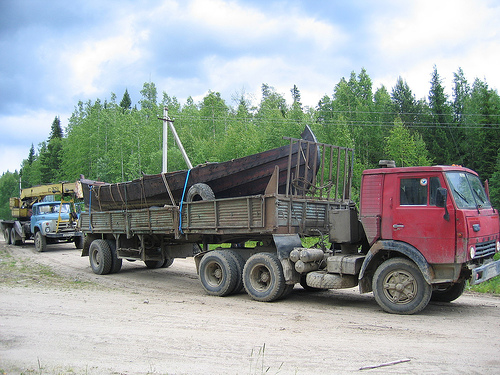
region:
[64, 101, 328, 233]
a boat out of water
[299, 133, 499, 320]
a dirty truck cab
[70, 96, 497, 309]
at least a 14 wheeler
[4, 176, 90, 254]
an old blue truck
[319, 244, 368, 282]
a large fuel tank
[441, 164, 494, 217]
visible windshield wiper path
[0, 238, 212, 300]
a muddy road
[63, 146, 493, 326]
a truck parked in a rural area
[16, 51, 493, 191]
a forest of evergreen trees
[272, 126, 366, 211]
a metal railing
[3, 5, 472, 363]
The picture is taken outside.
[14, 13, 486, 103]
The sky is blue with white clouds.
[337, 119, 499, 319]
The truck's cab is red in color.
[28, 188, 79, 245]
The truck's cab is blue in color.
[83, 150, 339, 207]
The truck is hauling a wood boat.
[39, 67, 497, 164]
The green trees are high and full of leaves.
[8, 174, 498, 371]
The truck are driving on dirt.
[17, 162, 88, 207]
The truck has a yellow crane on top.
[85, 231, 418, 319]
The truck's wheels are black but covered in dust and dirt.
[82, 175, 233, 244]
The straps holding the boat are blue in color.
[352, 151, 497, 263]
RED TRUCK CABIN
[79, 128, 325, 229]
TOWING AN OLD WOODEN BOAT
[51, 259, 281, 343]
WORN DIRT ROAD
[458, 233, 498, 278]
FRONT GRILLE OF A RED TRUCK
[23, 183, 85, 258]
BLUE TRUCK BEHIND LARGER TRUCK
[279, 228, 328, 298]
CYLINDERS LOADED ON TRUCK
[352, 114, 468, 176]
PINE TREES IN DISTANCE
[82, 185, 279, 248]
OLD STEEL FLATBED TRUCK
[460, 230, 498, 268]
HEADLIGHTS ON A RED TRUCK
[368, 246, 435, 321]
WHEEL CAP ON TRUCK TIRE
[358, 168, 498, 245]
the front of truck is red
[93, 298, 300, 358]
the ground is sandy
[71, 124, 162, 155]
the trees are green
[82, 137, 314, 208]
the boat is on the truck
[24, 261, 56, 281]
patches of grass on ground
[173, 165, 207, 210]
blue rope tying the boat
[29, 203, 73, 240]
the truck has a blue head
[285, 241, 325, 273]
three cylinders resting on the tire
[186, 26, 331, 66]
the sky is cloudy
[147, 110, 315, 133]
electric wires in the sky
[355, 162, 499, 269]
the cab of the front truck is red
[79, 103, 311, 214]
the truck is hauling a boat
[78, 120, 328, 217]
the boat is made of wood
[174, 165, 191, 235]
a blue rope holds the boat in place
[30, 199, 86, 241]
the cab of the truck in the back is light blue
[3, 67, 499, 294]
the trees behind the trucks are green and leafy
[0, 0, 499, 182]
the sky is bright with puffy white clouds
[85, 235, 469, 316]
the truck has many very dirty tires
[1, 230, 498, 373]
the road is dirt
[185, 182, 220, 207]
there is a tire in the bed of the truck next to the boat